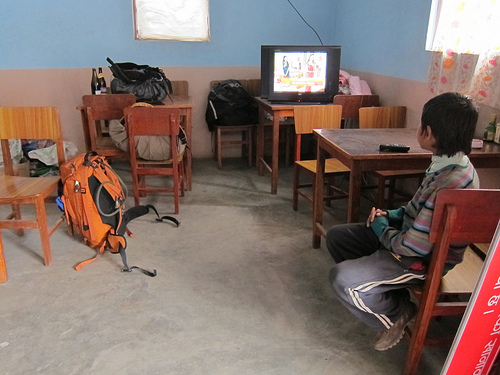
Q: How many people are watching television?
A: 1.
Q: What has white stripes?
A: Pants.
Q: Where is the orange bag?
A: Floor.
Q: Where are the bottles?
A: Table.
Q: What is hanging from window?
A: Curtains.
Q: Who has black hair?
A: Boy.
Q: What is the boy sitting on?
A: Chair.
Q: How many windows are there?
A: 2.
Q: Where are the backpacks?
A: By the chairs.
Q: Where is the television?
A: In the corner.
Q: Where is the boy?
A: By the table.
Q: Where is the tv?
A: On the other table.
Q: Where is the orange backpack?
A: By the chair.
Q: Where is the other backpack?
A: On the desk.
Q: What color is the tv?
A: Black.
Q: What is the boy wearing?
A: A shirt and pants.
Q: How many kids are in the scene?
A: One.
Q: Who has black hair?
A: The boy.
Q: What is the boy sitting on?
A: A chair.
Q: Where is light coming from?
A: Windows.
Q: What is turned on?
A: TV screen.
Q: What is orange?
A: Backpack.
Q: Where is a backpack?
A: On the floor.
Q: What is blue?
A: Walls.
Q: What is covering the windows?
A: Curtains.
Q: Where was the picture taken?
A: In a classroom.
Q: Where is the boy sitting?
A: In a chair.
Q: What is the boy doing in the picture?
A: Watching TV.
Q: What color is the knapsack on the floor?
A: Orange.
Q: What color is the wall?
A: Blue.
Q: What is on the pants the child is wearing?
A: A double white stripe.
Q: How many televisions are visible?
A: One.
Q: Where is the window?
A: To the right of the table the child is sitting at.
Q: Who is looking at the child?
A: The photographer.